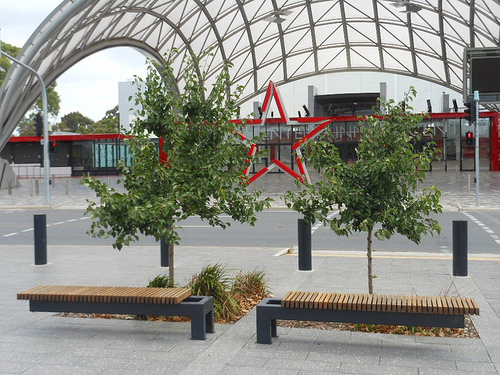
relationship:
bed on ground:
[16, 284, 214, 339] [5, 167, 499, 373]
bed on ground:
[255, 291, 480, 345] [5, 167, 499, 373]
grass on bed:
[234, 274, 268, 300] [255, 291, 480, 345]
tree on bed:
[282, 83, 445, 294] [274, 312, 481, 342]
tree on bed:
[77, 44, 272, 285] [53, 290, 266, 325]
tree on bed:
[282, 83, 445, 294] [16, 284, 214, 339]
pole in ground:
[449, 219, 471, 277] [5, 167, 499, 373]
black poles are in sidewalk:
[8, 211, 483, 287] [12, 261, 491, 367]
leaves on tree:
[97, 75, 453, 246] [78, 43, 272, 288]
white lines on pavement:
[455, 205, 499, 251] [0, 206, 499, 251]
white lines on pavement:
[310, 208, 347, 235] [0, 206, 499, 251]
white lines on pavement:
[6, 206, 101, 243] [0, 206, 499, 251]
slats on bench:
[280, 288, 480, 315] [247, 262, 499, 348]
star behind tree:
[202, 79, 334, 188] [277, 84, 444, 293]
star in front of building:
[219, 80, 336, 189] [0, 0, 500, 178]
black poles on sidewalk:
[34, 214, 48, 266] [12, 261, 491, 367]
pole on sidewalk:
[157, 232, 169, 267] [12, 261, 491, 367]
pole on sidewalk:
[297, 217, 315, 270] [12, 261, 491, 367]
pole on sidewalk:
[453, 220, 470, 277] [12, 261, 491, 367]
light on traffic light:
[466, 131, 470, 138] [465, 131, 473, 147]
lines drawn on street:
[59, 217, 74, 227] [1, 204, 498, 255]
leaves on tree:
[83, 43, 272, 249] [77, 44, 272, 285]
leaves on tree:
[285, 83, 442, 242] [282, 83, 445, 294]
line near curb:
[287, 250, 495, 260] [275, 251, 499, 262]